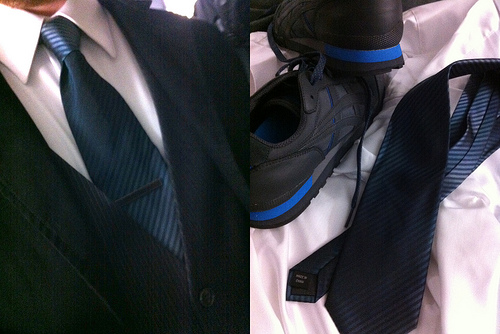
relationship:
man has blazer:
[2, 1, 248, 333] [0, 7, 250, 333]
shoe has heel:
[266, 1, 405, 78] [293, 41, 403, 72]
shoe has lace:
[252, 66, 391, 226] [345, 75, 371, 228]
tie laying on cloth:
[286, 58, 499, 333] [251, 0, 497, 333]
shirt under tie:
[1, 0, 166, 190] [35, 15, 186, 265]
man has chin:
[2, 1, 248, 333] [1, 0, 67, 14]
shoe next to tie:
[252, 66, 391, 226] [286, 58, 499, 333]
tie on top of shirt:
[35, 15, 186, 265] [1, 0, 166, 190]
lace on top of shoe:
[345, 75, 371, 228] [252, 66, 391, 226]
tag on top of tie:
[288, 271, 309, 288] [286, 58, 499, 333]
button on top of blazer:
[197, 287, 216, 309] [51, 17, 250, 333]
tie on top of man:
[35, 15, 186, 265] [2, 1, 248, 333]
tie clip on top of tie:
[114, 180, 161, 209] [35, 15, 186, 265]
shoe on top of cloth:
[266, 1, 405, 78] [251, 0, 497, 333]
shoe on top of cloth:
[252, 66, 391, 226] [251, 0, 497, 333]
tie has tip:
[286, 58, 499, 333] [289, 270, 317, 298]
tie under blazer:
[35, 15, 186, 265] [51, 17, 250, 333]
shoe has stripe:
[266, 1, 405, 78] [291, 38, 402, 61]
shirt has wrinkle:
[1, 0, 166, 190] [1, 67, 90, 181]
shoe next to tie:
[266, 1, 405, 78] [286, 58, 499, 333]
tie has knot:
[35, 15, 186, 265] [40, 16, 79, 60]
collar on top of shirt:
[1, 1, 117, 83] [1, 0, 166, 190]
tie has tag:
[286, 58, 499, 333] [288, 271, 309, 288]